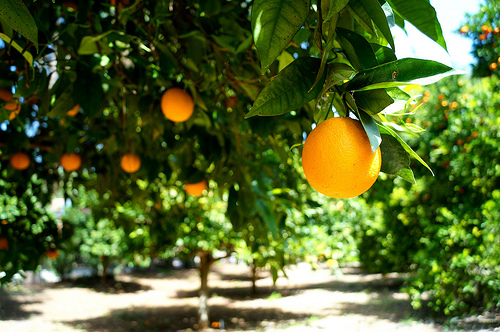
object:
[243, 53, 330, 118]
tree leaf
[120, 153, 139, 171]
orange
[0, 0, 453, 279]
tree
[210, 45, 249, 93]
tree limb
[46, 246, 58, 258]
orange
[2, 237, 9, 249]
orange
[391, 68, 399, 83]
bug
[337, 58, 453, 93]
leaf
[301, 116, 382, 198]
orange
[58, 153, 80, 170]
orange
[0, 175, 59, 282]
tree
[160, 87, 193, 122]
orange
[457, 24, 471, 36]
orange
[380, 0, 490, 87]
sky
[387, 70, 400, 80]
bug hole